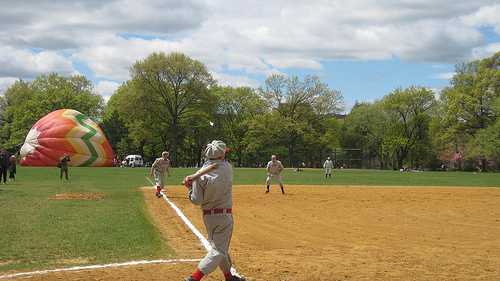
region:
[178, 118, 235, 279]
Person standing in field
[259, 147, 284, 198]
Person standing in field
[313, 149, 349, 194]
Person standing in field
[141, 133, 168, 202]
Person standing in field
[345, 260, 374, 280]
Small patch of brown dirt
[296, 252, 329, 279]
Small patch of brown dirt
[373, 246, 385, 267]
Small patch of brown dirt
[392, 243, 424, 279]
Small patch of brown dirt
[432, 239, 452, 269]
Small patch of brown dirt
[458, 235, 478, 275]
Small patch of brown dirt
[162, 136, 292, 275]
Baseball player swinging a bat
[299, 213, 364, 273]
The field is covered in dirt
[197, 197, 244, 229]
Baseball player wearing a belt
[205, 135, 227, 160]
Player is wearing a hat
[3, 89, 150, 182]
Parachute in the field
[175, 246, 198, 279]
Boy is wearing red socks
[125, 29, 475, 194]
Group of trees by the field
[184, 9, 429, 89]
Clouds in the sky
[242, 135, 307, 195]
Boy playing baseball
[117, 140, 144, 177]
White van by the parachute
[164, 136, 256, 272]
person holding the bat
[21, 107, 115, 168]
the balloon on the grass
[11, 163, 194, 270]
the grass on the field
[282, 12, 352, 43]
clouds in the sky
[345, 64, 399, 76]
the clear blue sky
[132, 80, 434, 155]
the trees with green leaves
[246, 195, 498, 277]
the dirt on the field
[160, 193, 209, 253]
the white line in the dirt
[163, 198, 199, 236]
the line is painted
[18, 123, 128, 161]
the balloon is deflating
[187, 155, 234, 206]
white baseball uniform shirt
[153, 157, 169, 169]
white baseball uniform shirt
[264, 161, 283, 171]
white baseball uniform shirt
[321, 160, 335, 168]
white baseball uniform shirt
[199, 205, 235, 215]
bright red colored belt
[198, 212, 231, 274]
grey colored baseball pant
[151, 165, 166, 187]
grey colored baseball pant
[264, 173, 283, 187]
grey colored baseball pant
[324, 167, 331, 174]
grey colored baseball pant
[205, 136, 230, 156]
grey colored baseball hat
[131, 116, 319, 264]
people playing base ball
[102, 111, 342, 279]
people playing on a field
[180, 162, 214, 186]
wooden base ball bat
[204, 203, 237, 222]
red belt on man's pants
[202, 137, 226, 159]
grey baseball hat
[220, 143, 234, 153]
red brim to grey hat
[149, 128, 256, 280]
man swinging a bat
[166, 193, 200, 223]
white chalk line on the ground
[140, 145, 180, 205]
man running down line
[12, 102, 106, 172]
hot air balloon on the ground